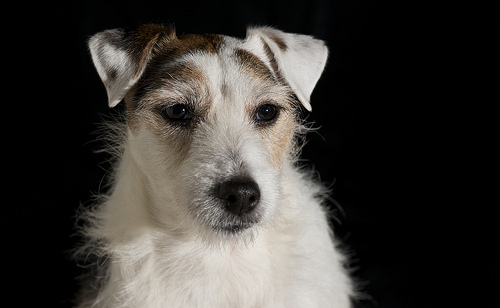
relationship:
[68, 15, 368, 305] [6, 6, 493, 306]
dog in picture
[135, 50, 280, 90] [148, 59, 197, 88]
forehead has marks